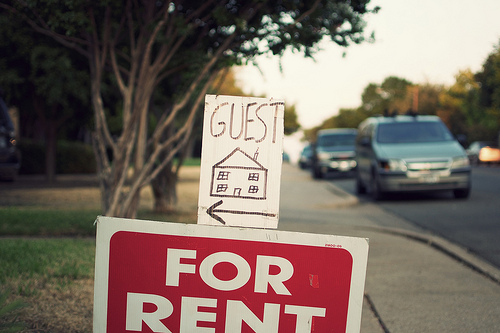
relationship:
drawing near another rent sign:
[200, 95, 281, 228] [96, 212, 373, 333]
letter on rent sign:
[174, 289, 220, 331] [96, 212, 373, 333]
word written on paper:
[209, 100, 285, 144] [188, 100, 288, 219]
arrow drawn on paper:
[205, 200, 276, 225] [195, 92, 284, 229]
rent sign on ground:
[96, 212, 373, 333] [0, 160, 497, 329]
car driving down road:
[353, 113, 472, 198] [433, 182, 499, 269]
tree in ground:
[0, 0, 376, 229] [12, 196, 182, 282]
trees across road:
[446, 42, 497, 147] [400, 200, 499, 247]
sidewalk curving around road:
[262, 143, 494, 323] [307, 123, 498, 268]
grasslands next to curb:
[1, 238, 99, 330] [294, 200, 495, 274]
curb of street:
[294, 200, 495, 274] [408, 181, 499, 245]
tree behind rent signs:
[0, 0, 376, 229] [84, 212, 374, 332]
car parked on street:
[353, 113, 472, 198] [414, 199, 499, 266]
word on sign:
[209, 100, 285, 144] [194, 84, 284, 224]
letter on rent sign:
[122, 287, 172, 332] [96, 212, 373, 333]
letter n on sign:
[89, 212, 370, 331] [222, 297, 281, 331]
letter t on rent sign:
[280, 301, 334, 332] [86, 216, 343, 329]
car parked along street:
[353, 113, 472, 198] [329, 160, 499, 269]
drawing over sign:
[200, 95, 281, 228] [78, 207, 408, 331]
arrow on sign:
[204, 200, 275, 225] [196, 94, 287, 234]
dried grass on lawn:
[13, 282, 86, 327] [5, 232, 84, 331]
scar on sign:
[293, 259, 320, 298] [69, 208, 336, 330]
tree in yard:
[79, 0, 379, 232] [0, 204, 195, 330]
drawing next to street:
[200, 95, 281, 228] [329, 160, 499, 269]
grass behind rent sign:
[6, 205, 176, 280] [96, 212, 373, 333]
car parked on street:
[348, 106, 473, 201] [274, 116, 498, 330]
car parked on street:
[311, 124, 357, 176] [274, 116, 498, 330]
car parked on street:
[353, 113, 472, 198] [409, 196, 498, 258]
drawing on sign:
[213, 142, 271, 227] [199, 88, 303, 244]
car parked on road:
[458, 135, 498, 165] [308, 102, 481, 261]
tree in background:
[0, 0, 376, 229] [10, 20, 484, 220]